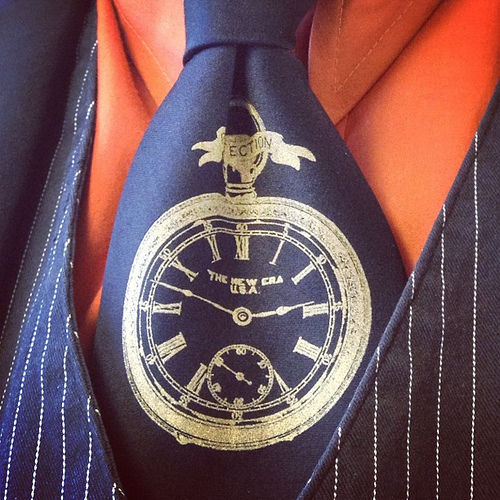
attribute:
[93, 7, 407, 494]
tie — blue and gold